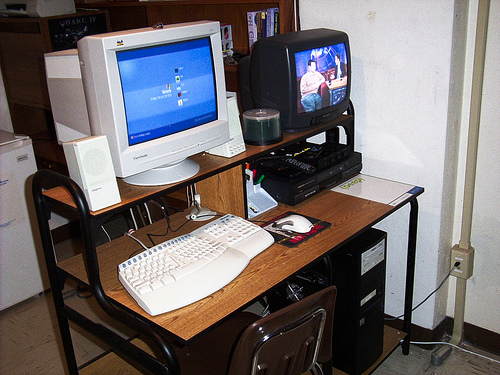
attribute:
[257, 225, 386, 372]
cpu — computer, black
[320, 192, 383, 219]
table surface — smooth, brown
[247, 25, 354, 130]
tv — small, black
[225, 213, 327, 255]
mouse — white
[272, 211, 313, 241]
mouse — computer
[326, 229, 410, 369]
computer — black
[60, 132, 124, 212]
speaker — tall, white, computer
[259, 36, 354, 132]
t.v — small, black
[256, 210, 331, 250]
mouse pad — black, red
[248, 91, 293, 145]
cd holder — clear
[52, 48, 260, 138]
computer — white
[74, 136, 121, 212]
speaker — white, computer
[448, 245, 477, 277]
outlet — beige, wall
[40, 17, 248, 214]
computer — white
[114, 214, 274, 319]
keyboard — white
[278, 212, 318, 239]
mouse — gray, white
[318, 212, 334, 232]
pad — mouse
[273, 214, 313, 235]
mouse — white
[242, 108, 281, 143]
discs — stack, digital, media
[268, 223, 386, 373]
tower — large, PC, black